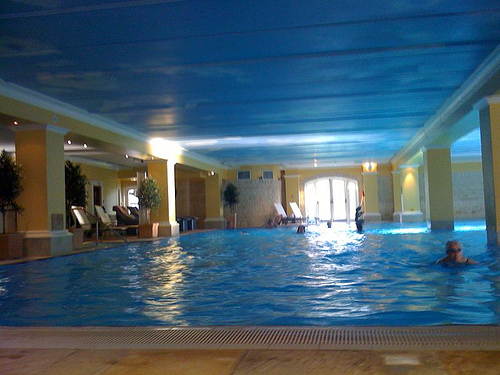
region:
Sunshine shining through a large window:
[299, 175, 364, 258]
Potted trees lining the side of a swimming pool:
[3, 147, 250, 260]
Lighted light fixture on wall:
[393, 162, 424, 199]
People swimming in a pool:
[291, 218, 483, 295]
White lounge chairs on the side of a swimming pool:
[71, 205, 137, 245]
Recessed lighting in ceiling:
[7, 110, 222, 195]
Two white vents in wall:
[233, 167, 278, 183]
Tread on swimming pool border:
[12, 325, 499, 355]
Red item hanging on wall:
[357, 185, 370, 201]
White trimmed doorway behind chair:
[88, 176, 109, 228]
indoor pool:
[10, 226, 499, 338]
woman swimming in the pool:
[436, 240, 472, 263]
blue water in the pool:
[0, 219, 495, 316]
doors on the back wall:
[296, 176, 363, 220]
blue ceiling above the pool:
[5, 2, 490, 174]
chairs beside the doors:
[267, 195, 319, 226]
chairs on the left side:
[63, 204, 175, 241]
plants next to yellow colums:
[0, 147, 240, 252]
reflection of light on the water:
[131, 234, 197, 320]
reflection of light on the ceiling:
[148, 100, 184, 135]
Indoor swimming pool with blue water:
[0, 212, 495, 323]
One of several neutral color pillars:
[413, 142, 460, 230]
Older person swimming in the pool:
[427, 232, 471, 280]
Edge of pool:
[0, 319, 491, 349]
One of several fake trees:
[59, 155, 94, 236]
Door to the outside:
[299, 172, 363, 223]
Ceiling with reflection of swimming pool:
[3, 0, 497, 174]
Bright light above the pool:
[143, 132, 193, 169]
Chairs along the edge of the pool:
[62, 186, 154, 240]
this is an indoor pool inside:
[161, 153, 383, 364]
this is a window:
[298, 157, 383, 238]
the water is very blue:
[156, 262, 279, 342]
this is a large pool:
[146, 195, 406, 358]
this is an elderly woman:
[435, 232, 485, 245]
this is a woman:
[410, 172, 486, 297]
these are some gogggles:
[405, 198, 478, 264]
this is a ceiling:
[297, 88, 354, 165]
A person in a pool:
[430, 238, 475, 269]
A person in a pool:
[351, 223, 368, 234]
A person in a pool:
[293, 224, 310, 234]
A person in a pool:
[323, 220, 335, 230]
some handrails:
[71, 205, 133, 247]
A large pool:
[3, 215, 498, 323]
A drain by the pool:
[1, 323, 496, 348]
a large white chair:
[272, 201, 306, 222]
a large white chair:
[288, 201, 319, 221]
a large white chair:
[95, 205, 140, 230]